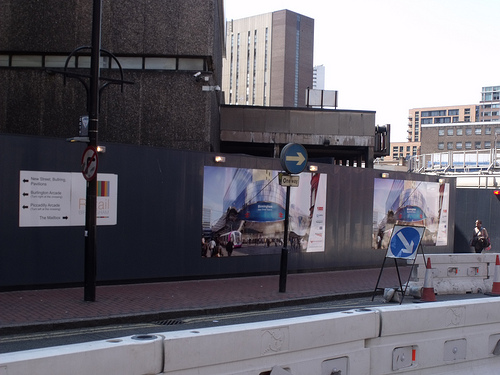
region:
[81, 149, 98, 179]
white and red sign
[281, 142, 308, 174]
blue and white sign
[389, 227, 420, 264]
blue sign on ground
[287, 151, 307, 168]
white arrow on sign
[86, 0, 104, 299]
black iron lamp post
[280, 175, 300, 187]
white sign on post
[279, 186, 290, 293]
black iron sign post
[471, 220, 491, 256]
person walking on side walk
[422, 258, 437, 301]
orange and white cone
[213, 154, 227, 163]
white light on wall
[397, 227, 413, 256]
the arrow is white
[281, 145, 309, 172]
the sign is blue and white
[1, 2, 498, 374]
the scene takes outdoors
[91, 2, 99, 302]
the pole is black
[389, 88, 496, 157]
the building has many windows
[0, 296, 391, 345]
the street has lines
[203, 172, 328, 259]
the wall has a poster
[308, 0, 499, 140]
the sky is clear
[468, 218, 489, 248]
a person is walking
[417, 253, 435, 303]
the cone is orange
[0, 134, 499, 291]
a gray construction barrier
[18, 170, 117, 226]
a sign on the gray wall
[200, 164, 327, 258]
a sign on the gray wall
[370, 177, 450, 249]
a sign on the gray wall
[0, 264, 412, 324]
a red cobblestone sidewalk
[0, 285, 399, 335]
a concrete curb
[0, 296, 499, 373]
a white construction barrier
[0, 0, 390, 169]
a building behind the wall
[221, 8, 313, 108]
a building in the background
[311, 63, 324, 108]
a white building in the background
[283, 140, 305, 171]
Blue and white sign pointing right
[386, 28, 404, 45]
Small part of the white sky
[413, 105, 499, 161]
Buildings in the background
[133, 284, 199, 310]
Small section of the brown brick sidewalk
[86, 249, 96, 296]
Bottom of the black pole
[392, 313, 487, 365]
Medium section of the white barricade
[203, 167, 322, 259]
Poster on the black wall mat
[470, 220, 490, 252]
Pedestrian walking on the sidewalk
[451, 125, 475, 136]
Two windows on the brown building in the distance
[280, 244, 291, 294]
Bottom part of the black pole that connects to sign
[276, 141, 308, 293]
blue street sign with a white arrow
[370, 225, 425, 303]
blue street sign with a white arrow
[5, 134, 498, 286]
grey wall beside a sidewalk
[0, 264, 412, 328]
a brick sidewalk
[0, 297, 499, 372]
a white temporary barrier wall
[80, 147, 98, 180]
street sign on a metal post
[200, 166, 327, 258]
large poster on a wall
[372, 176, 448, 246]
large poster on a wall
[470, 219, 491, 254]
someone walking down a brick sidewalk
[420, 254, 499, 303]
two orange traffic cones